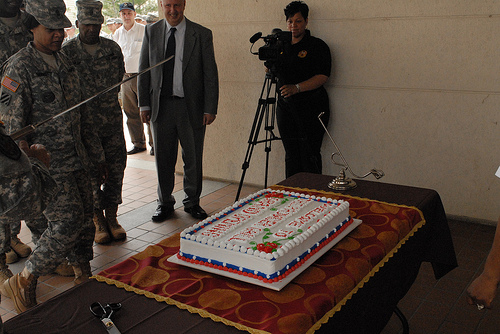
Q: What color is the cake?
A: Red, white, blue, and green.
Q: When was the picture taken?
A: Daytime.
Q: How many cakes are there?
A: One.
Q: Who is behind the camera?
A: The woman.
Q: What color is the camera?
A: Black.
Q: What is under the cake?
A: The tablecloth.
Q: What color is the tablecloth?
A: Brown and black.